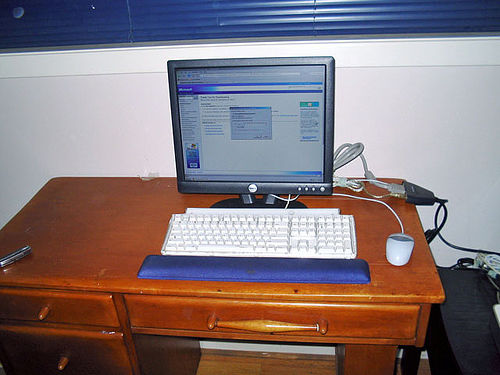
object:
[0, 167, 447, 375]
wood desk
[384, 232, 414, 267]
computer mouse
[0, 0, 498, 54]
blinds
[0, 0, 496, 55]
window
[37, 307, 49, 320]
knob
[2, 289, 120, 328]
drawer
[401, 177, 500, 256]
hook up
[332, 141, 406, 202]
hook up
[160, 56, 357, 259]
computer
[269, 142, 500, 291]
cables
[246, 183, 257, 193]
silver button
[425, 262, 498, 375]
tower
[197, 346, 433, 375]
floor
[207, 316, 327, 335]
handle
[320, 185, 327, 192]
button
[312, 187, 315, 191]
button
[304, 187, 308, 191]
button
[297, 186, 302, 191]
button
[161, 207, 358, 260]
keyboard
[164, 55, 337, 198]
computer monitor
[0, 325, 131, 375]
door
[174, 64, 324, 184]
monitor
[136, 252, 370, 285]
wrist support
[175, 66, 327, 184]
screen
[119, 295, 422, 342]
desk drawer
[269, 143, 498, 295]
wire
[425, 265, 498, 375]
pc tower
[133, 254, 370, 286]
pad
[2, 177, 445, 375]
table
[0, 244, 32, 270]
item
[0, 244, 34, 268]
army knife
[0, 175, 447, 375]
desk